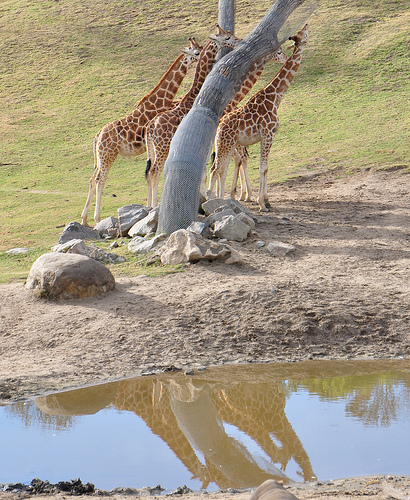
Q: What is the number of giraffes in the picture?
A: Four.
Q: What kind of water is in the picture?
A: Murk and reflective.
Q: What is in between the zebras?
A: A tree.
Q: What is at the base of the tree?
A: Rocks.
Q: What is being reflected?
A: The animals.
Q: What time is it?
A: Afternoon.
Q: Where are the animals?
A: On the land.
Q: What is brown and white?
A: Giraffes.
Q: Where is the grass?
A: Next to giraffes.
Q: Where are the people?
A: No people in photo.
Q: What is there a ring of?
A: Gray rocks.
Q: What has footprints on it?
A: The dirt.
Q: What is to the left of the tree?
A: Two giraffes eating.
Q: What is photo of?
A: Herd of giraffes.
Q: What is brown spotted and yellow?
A: Herd of giraffe.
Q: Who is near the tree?
A: Herd of yellow and brown giraffe.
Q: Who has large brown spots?
A: Herd of giraffe.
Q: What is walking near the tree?
A: Herd of giraffe.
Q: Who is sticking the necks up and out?
A: Herd of giraffes.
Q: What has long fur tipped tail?
A: Herd of yellow and brown giraffe.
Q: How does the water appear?
A: Murky.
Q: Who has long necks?
A: The giraffe.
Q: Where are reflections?
A: On the water.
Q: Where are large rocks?
A: On the ground.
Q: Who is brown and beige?
A: The giraffe.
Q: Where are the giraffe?
A: Near a tree.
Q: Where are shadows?
A: On the dirt.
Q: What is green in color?
A: Grass.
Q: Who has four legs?
A: One giraffe.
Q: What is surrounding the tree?
A: Large rocks.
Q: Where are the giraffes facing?
A: One way.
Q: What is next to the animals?
A: Water.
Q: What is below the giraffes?
A: Grass.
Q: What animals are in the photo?
A: Giraffes.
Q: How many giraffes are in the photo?
A: Four.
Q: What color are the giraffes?
A: Brown, Yellow.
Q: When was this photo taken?
A: Daytime.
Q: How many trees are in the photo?
A: One.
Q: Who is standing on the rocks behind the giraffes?
A: No one.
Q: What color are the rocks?
A: Grey.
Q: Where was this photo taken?
A: In a zoo.